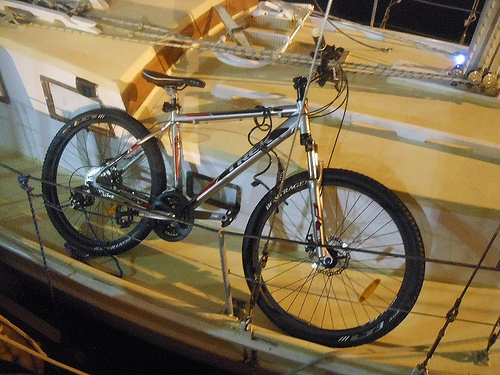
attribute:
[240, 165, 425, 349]
wheel — part, edge, black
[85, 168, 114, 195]
metal — part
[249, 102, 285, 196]
wire — part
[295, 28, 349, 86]
steering — part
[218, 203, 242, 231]
pedal — part, black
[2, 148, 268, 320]
shadow — part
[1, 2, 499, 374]
boat — tan, wood, small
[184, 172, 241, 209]
window — part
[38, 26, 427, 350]
bike — silver, red, black, orange, brand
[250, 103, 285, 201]
lock — black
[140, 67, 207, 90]
seat — flat, black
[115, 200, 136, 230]
pedal — black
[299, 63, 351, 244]
cables — black